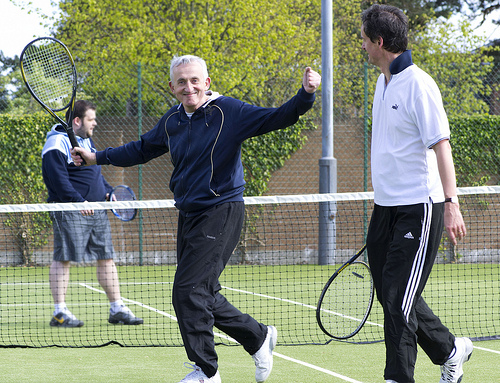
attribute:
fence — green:
[0, 58, 498, 265]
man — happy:
[117, 50, 334, 372]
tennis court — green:
[1, 264, 498, 380]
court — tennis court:
[14, 14, 497, 371]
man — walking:
[145, 53, 338, 359]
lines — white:
[257, 288, 367, 329]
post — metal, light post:
[307, 2, 348, 269]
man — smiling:
[104, 22, 306, 379]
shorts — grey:
[43, 198, 115, 262]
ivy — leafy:
[4, 114, 489, 217]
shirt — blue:
[127, 67, 323, 198]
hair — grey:
[142, 45, 222, 84]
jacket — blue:
[83, 97, 317, 203]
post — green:
[131, 56, 375, 269]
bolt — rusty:
[324, 207, 336, 225]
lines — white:
[65, 272, 427, 375]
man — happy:
[71, 47, 329, 381]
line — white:
[279, 351, 365, 380]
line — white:
[237, 281, 309, 310]